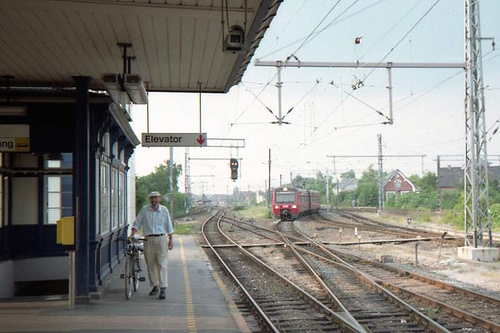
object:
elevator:
[145, 135, 183, 144]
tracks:
[196, 204, 498, 333]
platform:
[1, 236, 246, 332]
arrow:
[195, 133, 205, 145]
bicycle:
[116, 237, 145, 304]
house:
[376, 168, 419, 208]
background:
[131, 4, 497, 241]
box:
[55, 216, 75, 247]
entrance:
[1, 251, 74, 302]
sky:
[131, 0, 500, 190]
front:
[271, 185, 298, 217]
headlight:
[274, 206, 279, 210]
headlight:
[291, 205, 297, 209]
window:
[275, 187, 297, 202]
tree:
[354, 168, 383, 207]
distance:
[139, 1, 499, 187]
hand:
[166, 239, 174, 250]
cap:
[148, 191, 161, 197]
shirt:
[130, 203, 174, 237]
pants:
[142, 233, 168, 287]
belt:
[144, 232, 165, 237]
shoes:
[148, 286, 159, 296]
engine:
[269, 188, 322, 219]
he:
[128, 192, 175, 299]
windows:
[9, 154, 71, 223]